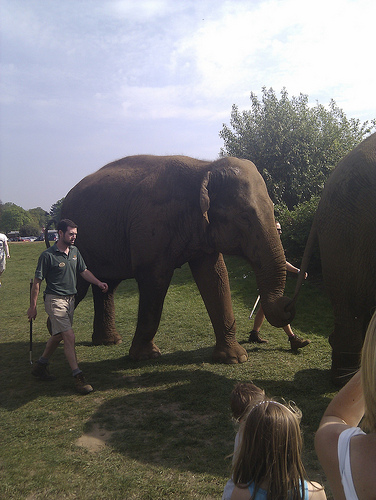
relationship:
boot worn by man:
[71, 372, 94, 394] [27, 218, 109, 394]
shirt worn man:
[34, 240, 87, 296] [27, 218, 109, 394]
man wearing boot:
[27, 218, 109, 394] [277, 321, 312, 358]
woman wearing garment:
[322, 251, 373, 484] [309, 399, 357, 476]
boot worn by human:
[247, 329, 270, 342] [247, 217, 309, 348]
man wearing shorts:
[19, 210, 111, 398] [38, 287, 85, 336]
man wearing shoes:
[27, 218, 109, 394] [28, 353, 94, 393]